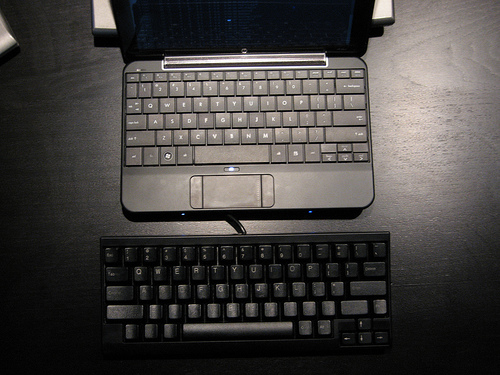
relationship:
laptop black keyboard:
[107, 49, 384, 209] [155, 100, 337, 153]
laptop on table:
[107, 49, 384, 209] [392, 67, 436, 108]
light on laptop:
[306, 207, 318, 216] [107, 49, 384, 209]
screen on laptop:
[161, 5, 348, 52] [107, 49, 384, 209]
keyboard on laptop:
[155, 100, 337, 153] [107, 49, 384, 209]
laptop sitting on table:
[107, 49, 384, 209] [392, 67, 436, 108]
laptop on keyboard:
[107, 49, 384, 209] [155, 100, 337, 153]